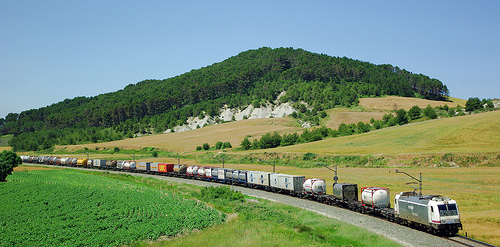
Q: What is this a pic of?
A: A train.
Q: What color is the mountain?
A: Green.